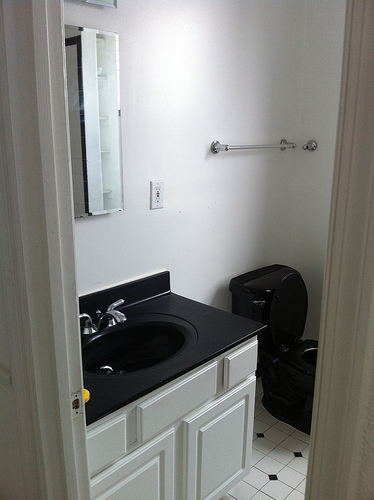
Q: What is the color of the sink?
A: Black.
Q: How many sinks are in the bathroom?
A: One.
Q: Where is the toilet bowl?
A: Beside the sink.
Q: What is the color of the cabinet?
A: White.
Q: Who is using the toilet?
A: No one.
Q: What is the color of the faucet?
A: Silver.